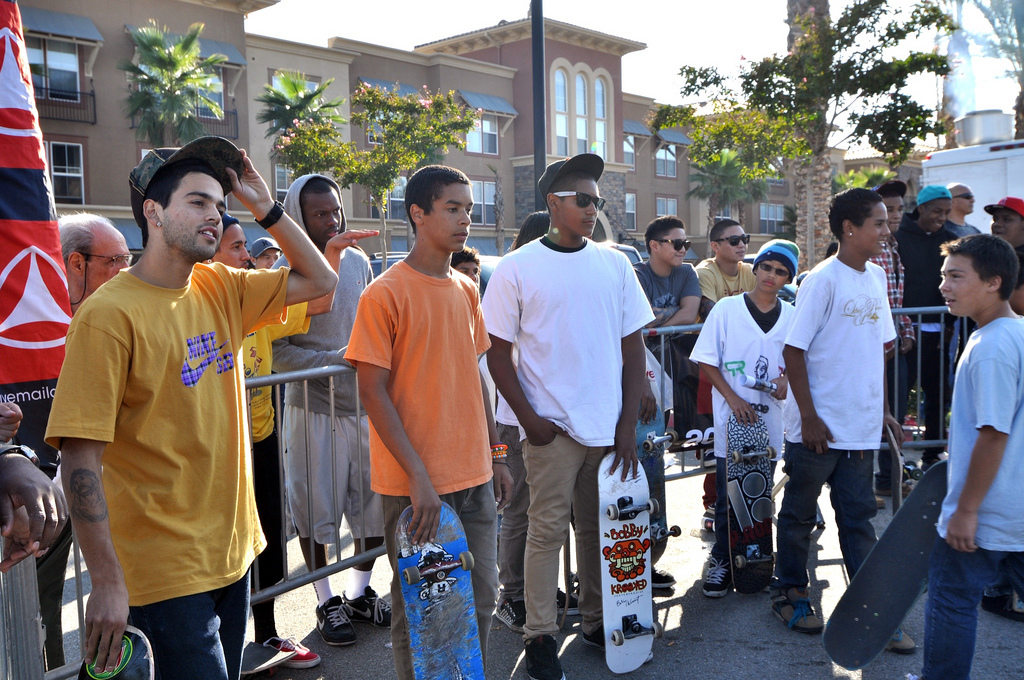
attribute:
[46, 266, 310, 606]
shirt — yellow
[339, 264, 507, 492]
shirt — orange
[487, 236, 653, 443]
shirt — white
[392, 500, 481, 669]
skateboar — blue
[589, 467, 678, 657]
board — blue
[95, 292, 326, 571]
shirt — white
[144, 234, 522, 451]
people — many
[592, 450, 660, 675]
skateboard — white, orange